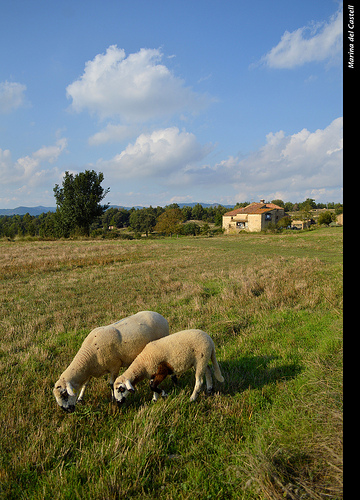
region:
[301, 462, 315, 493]
the grass is green and brown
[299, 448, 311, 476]
the grass is green and brown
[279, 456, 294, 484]
the grass is green and brown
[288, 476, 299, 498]
the grass is green and brown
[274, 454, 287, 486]
the grass is green and brown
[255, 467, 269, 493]
the grass is green and brown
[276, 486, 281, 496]
the grass is green and brown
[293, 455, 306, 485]
the grass is green and brown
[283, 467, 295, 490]
the grass is green and brown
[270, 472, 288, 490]
the grass is green and brown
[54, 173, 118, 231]
this is a tree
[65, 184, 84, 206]
the tree has green leaves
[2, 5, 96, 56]
this is the sky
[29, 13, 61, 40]
the sky is blue in color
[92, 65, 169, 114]
this is the cloud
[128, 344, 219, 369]
this is a sheep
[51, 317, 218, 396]
there are two sheep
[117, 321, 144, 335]
the wool is white in color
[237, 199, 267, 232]
this is a house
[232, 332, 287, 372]
this is a grass area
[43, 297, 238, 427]
two sheep grazing in field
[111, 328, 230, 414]
sheep with one brown leg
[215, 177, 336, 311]
yellow house in a field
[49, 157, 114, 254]
tree with green leaves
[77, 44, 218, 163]
white cloud in blue sky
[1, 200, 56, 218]
mountains in the distance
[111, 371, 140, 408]
head of sheep grazing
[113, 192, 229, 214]
mountain range on horizen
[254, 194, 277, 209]
chimney on a red roof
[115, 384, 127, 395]
sheep's eye with black markings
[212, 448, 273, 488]
the grass is waving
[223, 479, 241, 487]
the grass is waving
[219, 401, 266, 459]
the grass is waving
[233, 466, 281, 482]
the grass is waving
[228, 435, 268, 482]
the grass is waving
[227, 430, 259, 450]
the grass is waving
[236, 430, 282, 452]
the grass is waving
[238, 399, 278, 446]
the grass is waving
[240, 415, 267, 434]
the grass is waving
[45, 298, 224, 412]
these are two sheep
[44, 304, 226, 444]
the sheep are feeding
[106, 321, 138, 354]
the wool is white in color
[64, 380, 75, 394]
this is the ear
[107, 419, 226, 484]
the grass is green in color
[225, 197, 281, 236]
this is a house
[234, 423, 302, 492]
the grass is long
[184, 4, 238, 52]
the sky is blue in color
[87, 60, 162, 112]
the clouds are white in color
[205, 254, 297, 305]
the grass are brown in color